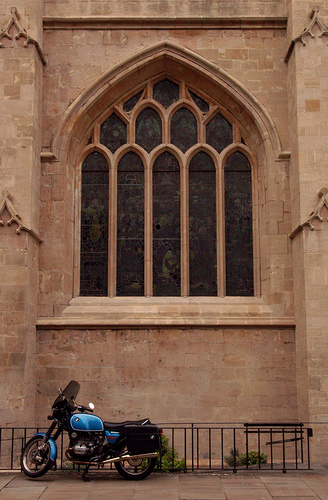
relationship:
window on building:
[189, 250, 219, 286] [40, 19, 298, 383]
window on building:
[151, 259, 170, 292] [57, 14, 309, 357]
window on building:
[80, 237, 102, 280] [55, 30, 308, 376]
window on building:
[169, 112, 197, 147] [52, 22, 287, 372]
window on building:
[139, 120, 166, 145] [48, 9, 315, 403]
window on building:
[99, 115, 124, 149] [55, 30, 308, 376]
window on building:
[156, 85, 173, 100] [55, 30, 308, 376]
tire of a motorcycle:
[14, 429, 58, 474] [23, 373, 176, 491]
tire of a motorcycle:
[18, 429, 58, 478] [11, 364, 169, 485]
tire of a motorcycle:
[18, 429, 58, 478] [19, 378, 165, 486]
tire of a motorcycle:
[18, 429, 58, 478] [4, 376, 178, 482]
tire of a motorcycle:
[110, 436, 158, 481] [4, 386, 148, 484]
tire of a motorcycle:
[110, 436, 158, 481] [23, 373, 176, 491]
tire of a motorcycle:
[110, 436, 158, 481] [5, 382, 177, 498]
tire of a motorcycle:
[110, 436, 158, 481] [9, 373, 168, 491]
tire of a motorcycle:
[109, 437, 177, 484] [23, 383, 163, 483]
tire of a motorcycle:
[18, 429, 58, 478] [31, 371, 193, 487]